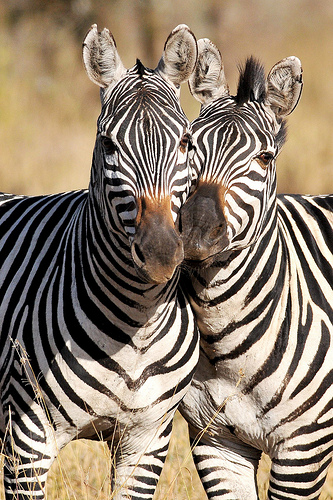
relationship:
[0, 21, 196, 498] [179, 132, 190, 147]
zebra has right eye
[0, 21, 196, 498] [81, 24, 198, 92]
zebra has ears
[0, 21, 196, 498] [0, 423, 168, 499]
zebra has legs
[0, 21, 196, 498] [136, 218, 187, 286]
zebra has nose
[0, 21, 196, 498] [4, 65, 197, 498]
zebra has stripes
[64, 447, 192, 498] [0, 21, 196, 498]
grass below zebra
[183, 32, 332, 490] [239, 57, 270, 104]
zebra has hair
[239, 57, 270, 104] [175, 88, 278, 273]
hair at top of head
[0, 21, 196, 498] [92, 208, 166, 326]
zebra has neck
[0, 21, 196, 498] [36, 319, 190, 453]
zebra has torso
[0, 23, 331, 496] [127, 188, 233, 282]
zebras have noses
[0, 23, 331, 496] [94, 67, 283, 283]
zebras have faces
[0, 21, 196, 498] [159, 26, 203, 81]
zebra has right ear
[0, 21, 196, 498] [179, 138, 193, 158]
zebra has right eye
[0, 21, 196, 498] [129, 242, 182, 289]
zebra has mouth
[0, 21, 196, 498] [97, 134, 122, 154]
zebra has left eye